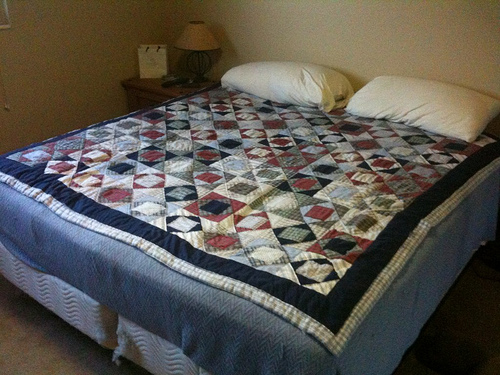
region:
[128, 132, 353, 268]
patterned quilt on the bed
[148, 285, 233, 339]
blue blanket on the bed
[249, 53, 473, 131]
white pillows on the bed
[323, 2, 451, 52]
tan walls of the room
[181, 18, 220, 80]
lamp on a nightstand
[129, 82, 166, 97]
brown wood nightstand next to the bed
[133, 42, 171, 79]
white bag sitting on the nightstand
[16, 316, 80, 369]
beige carpet of the ground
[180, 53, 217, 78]
black metal base of the lamp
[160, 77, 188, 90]
black remote control on the nightstand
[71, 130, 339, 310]
this is a bed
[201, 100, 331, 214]
this is the blanket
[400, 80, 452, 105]
this is a pillow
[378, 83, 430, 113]
the pillow is white in color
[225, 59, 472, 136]
the pillow are two in number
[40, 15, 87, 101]
this is the wall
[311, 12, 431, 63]
the wall is white in color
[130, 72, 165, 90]
this is a table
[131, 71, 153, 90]
the table is wooden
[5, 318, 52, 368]
this is the floor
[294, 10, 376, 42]
this is the wall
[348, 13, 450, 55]
the wall is white in color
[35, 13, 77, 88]
the wall is clean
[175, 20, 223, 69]
this is a lamp shade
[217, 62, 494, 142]
these are two pillows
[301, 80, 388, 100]
the pillows are white in color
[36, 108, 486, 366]
this is a bed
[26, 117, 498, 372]
the bed is big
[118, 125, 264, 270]
this is a bed cover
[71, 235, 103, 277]
the bed cover is blue in color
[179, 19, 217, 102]
a small lamp on a table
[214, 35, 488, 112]
two pillows on a bed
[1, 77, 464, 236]
a quilt on a bed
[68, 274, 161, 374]
two beds pushed together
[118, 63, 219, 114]
a bedside table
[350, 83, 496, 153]
a pillow in a white pillow case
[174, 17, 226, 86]
a lamp with a white shade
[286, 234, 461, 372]
a blue sheet on a bed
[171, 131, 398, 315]
a quilt with a pattern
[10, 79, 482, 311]
a bed covered with a quilt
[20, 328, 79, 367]
tan carpet of the floor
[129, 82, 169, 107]
brown wooden nightstand next to the bed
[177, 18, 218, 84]
white lamp on the nightstand